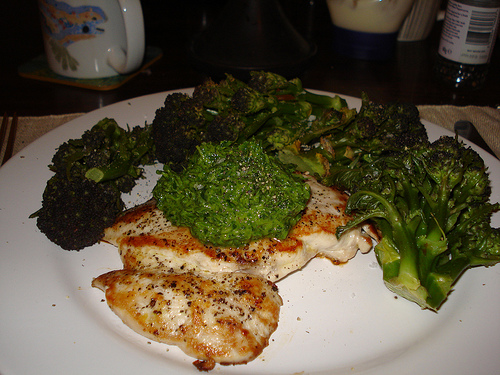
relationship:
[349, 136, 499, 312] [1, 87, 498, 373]
broccoli on a plate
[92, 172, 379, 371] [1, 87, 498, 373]
chicken on a plate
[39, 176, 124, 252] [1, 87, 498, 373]
broccoli on a plate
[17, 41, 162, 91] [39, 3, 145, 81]
coaster under a mug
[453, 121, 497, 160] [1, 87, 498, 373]
knife beside a plate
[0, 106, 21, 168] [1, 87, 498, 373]
fork beside a plate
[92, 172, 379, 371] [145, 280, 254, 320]
meat has seasoning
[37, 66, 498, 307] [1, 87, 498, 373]
vegetable on a plate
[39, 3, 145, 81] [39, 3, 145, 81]
cup for coffee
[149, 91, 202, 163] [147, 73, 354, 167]
piece of broccoli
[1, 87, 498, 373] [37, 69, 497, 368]
plate of food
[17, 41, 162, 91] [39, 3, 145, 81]
coaster for a drink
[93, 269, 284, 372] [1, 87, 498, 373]
meat on a plate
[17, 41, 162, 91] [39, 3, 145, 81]
coaster for cups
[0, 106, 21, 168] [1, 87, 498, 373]
silverware beside a plate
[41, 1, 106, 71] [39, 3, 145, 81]
design on a cup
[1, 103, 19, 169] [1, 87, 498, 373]
chopsticks beside a plate